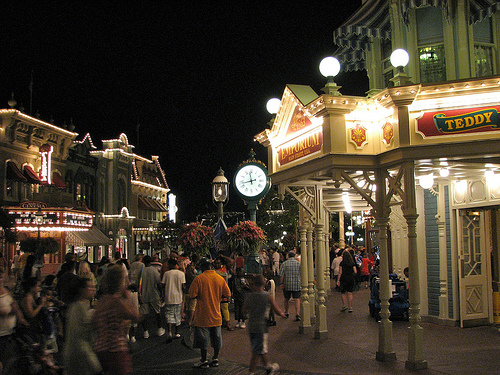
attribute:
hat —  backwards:
[195, 249, 215, 264]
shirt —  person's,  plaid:
[278, 258, 303, 293]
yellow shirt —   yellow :
[188, 270, 232, 332]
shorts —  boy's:
[283, 285, 310, 326]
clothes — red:
[82, 259, 145, 374]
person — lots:
[188, 257, 232, 372]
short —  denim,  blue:
[193, 323, 221, 349]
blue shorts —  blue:
[183, 309, 229, 355]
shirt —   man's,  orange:
[193, 274, 229, 333]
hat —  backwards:
[193, 254, 210, 265]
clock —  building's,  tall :
[237, 158, 272, 198]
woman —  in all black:
[337, 249, 358, 314]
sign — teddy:
[434, 103, 499, 132]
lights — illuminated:
[265, 60, 436, 167]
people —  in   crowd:
[93, 245, 182, 342]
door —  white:
[456, 206, 498, 326]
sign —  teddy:
[414, 106, 496, 136]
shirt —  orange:
[184, 272, 231, 329]